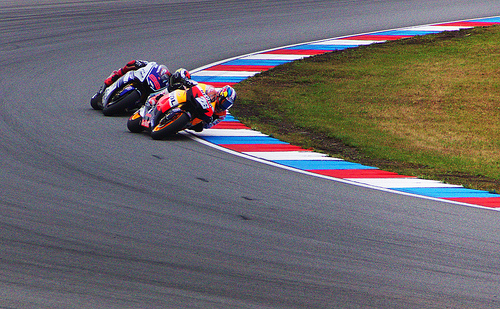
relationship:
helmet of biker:
[217, 83, 235, 104] [146, 84, 236, 125]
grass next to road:
[230, 26, 499, 195] [69, 180, 298, 292]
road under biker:
[0, 0, 499, 309] [147, 79, 244, 149]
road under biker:
[0, 0, 499, 309] [97, 51, 169, 113]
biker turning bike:
[193, 83, 235, 130] [127, 83, 214, 136]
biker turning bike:
[99, 60, 191, 95] [89, 57, 171, 116]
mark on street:
[191, 170, 212, 182] [4, 0, 499, 308]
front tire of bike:
[104, 85, 136, 100] [82, 50, 143, 118]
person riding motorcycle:
[104, 58, 193, 88] [126, 77, 240, 139]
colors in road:
[183, 14, 498, 213] [6, 7, 494, 302]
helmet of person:
[217, 85, 237, 109] [169, 87, 242, 114]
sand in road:
[367, 46, 496, 176] [6, 7, 494, 302]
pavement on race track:
[7, 0, 497, 302] [0, 0, 497, 307]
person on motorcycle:
[145, 80, 237, 133] [127, 82, 206, 152]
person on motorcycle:
[104, 59, 195, 93] [90, 60, 169, 115]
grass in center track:
[230, 26, 499, 195] [5, 1, 412, 307]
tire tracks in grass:
[236, 52, 437, 174] [352, 37, 424, 120]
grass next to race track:
[283, 42, 492, 179] [1, 1, 289, 304]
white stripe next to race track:
[344, 176, 458, 187] [0, 0, 497, 307]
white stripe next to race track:
[247, 151, 340, 161] [0, 0, 497, 307]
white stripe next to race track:
[181, 128, 268, 135] [0, 0, 497, 307]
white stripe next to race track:
[192, 68, 266, 78] [0, 0, 497, 307]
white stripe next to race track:
[241, 52, 315, 62] [0, 0, 497, 307]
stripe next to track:
[183, 9, 495, 224] [6, 67, 136, 265]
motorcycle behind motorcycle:
[125, 80, 236, 142] [85, 54, 173, 115]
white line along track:
[195, 8, 499, 216] [3, 2, 499, 307]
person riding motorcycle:
[104, 59, 195, 93] [92, 65, 144, 116]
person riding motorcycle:
[171, 74, 232, 119] [146, 92, 202, 128]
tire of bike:
[148, 107, 195, 137] [122, 74, 236, 144]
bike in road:
[130, 79, 248, 155] [6, 7, 494, 302]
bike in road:
[101, 50, 197, 122] [6, 7, 494, 302]